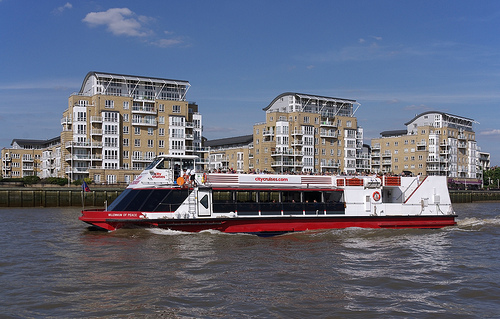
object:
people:
[218, 167, 223, 173]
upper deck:
[195, 166, 420, 191]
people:
[324, 170, 331, 176]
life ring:
[372, 191, 380, 201]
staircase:
[381, 175, 428, 205]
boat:
[78, 155, 458, 237]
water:
[401, 269, 435, 300]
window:
[111, 189, 193, 213]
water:
[0, 295, 108, 319]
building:
[0, 71, 211, 186]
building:
[201, 91, 372, 188]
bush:
[484, 166, 495, 190]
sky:
[393, 1, 500, 38]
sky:
[139, 29, 231, 45]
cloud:
[80, 7, 190, 49]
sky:
[286, 31, 342, 52]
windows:
[102, 111, 121, 169]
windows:
[302, 189, 326, 215]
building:
[369, 110, 491, 191]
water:
[0, 229, 44, 257]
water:
[144, 277, 178, 306]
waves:
[357, 266, 417, 284]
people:
[190, 169, 197, 188]